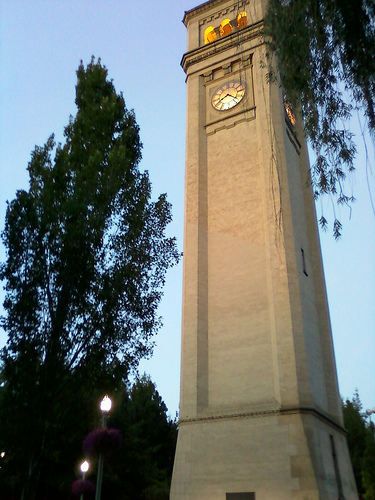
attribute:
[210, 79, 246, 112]
clock — illuminated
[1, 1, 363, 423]
sky — clear, blue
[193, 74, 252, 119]
clock — lit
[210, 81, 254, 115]
clock — round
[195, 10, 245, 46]
light — orange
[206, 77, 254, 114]
clock — lit up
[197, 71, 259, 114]
clock — illuminated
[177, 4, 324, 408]
tower — tall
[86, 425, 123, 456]
flowers — purple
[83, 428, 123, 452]
flowers — purple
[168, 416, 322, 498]
stone base — large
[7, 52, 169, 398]
tree — tall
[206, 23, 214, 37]
light — yellow 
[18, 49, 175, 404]
tree — tall, green, leafy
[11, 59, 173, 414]
tree — tall, green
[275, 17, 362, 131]
tree — green, leafy, large